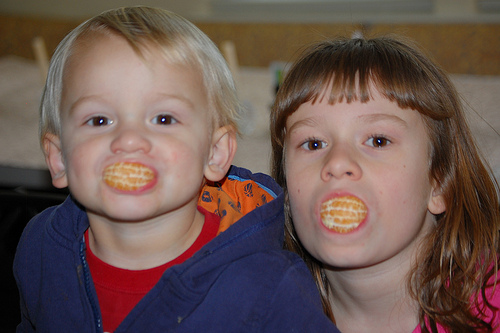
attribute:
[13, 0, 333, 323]
child — seeing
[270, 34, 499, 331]
child — seeing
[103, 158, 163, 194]
mouth — boy's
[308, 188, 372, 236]
mouth — girl's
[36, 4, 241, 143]
hair — boy's, blond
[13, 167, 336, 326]
jacket — blue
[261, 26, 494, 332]
girl — young, here, light skinned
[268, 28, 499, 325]
hair — brown, here, long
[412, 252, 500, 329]
dress — pink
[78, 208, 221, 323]
shirt — red, inner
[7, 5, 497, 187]
wall — brown, here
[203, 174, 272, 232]
lining — orange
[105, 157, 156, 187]
piece — orange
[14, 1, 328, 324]
boy — young, here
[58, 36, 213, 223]
face — boy's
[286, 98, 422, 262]
face — girl's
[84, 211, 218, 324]
t-shirt — here, red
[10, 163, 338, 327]
pullover — here, blue